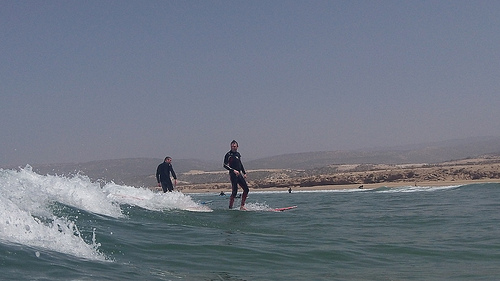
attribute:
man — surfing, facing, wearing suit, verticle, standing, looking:
[223, 139, 254, 212]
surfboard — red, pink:
[233, 202, 301, 214]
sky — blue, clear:
[2, 1, 498, 138]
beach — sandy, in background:
[387, 179, 414, 187]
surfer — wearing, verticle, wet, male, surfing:
[156, 154, 183, 191]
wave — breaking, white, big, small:
[108, 180, 166, 213]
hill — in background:
[341, 162, 397, 184]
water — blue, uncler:
[298, 190, 357, 233]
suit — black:
[224, 152, 259, 207]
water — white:
[109, 187, 151, 202]